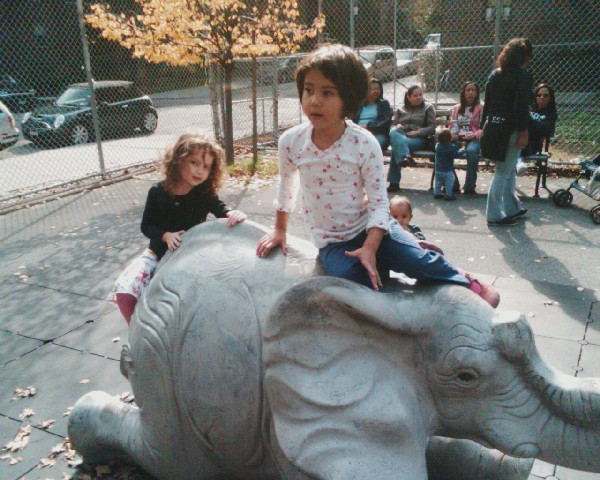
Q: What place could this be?
A: It is a park.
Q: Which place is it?
A: It is a park.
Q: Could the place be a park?
A: Yes, it is a park.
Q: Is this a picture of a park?
A: Yes, it is showing a park.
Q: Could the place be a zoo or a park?
A: It is a park.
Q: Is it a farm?
A: No, it is a park.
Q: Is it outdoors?
A: Yes, it is outdoors.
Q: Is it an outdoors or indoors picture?
A: It is outdoors.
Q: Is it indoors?
A: No, it is outdoors.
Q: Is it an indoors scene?
A: No, it is outdoors.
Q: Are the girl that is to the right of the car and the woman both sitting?
A: Yes, both the girl and the woman are sitting.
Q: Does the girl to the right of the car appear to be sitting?
A: Yes, the girl is sitting.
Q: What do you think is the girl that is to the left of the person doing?
A: The girl is sitting.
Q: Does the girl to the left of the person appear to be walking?
A: No, the girl is sitting.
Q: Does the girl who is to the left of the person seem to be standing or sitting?
A: The girl is sitting.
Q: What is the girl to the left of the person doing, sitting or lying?
A: The girl is sitting.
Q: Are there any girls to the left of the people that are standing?
A: Yes, there is a girl to the left of the people.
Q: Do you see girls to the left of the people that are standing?
A: Yes, there is a girl to the left of the people.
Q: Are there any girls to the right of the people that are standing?
A: No, the girl is to the left of the people.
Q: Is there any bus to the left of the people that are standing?
A: No, there is a girl to the left of the people.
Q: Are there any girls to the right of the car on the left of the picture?
A: Yes, there is a girl to the right of the car.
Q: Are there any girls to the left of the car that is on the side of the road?
A: No, the girl is to the right of the car.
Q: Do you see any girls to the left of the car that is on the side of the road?
A: No, the girl is to the right of the car.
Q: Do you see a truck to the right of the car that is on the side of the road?
A: No, there is a girl to the right of the car.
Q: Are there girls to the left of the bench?
A: Yes, there is a girl to the left of the bench.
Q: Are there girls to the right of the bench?
A: No, the girl is to the left of the bench.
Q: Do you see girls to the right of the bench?
A: No, the girl is to the left of the bench.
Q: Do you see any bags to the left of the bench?
A: No, there is a girl to the left of the bench.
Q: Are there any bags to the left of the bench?
A: No, there is a girl to the left of the bench.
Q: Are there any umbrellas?
A: No, there are no umbrellas.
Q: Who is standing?
A: The people are standing.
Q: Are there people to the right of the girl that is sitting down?
A: Yes, there are people to the right of the girl.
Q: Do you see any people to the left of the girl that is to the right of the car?
A: No, the people are to the right of the girl.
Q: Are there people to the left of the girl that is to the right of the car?
A: No, the people are to the right of the girl.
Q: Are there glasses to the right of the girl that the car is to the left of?
A: No, there are people to the right of the girl.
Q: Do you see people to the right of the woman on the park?
A: Yes, there are people to the right of the woman.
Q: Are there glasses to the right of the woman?
A: No, there are people to the right of the woman.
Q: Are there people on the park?
A: Yes, there are people on the park.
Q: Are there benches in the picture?
A: Yes, there is a bench.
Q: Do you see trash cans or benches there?
A: Yes, there is a bench.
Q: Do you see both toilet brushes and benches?
A: No, there is a bench but no toilet brushes.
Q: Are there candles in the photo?
A: No, there are no candles.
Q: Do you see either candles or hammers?
A: No, there are no candles or hammers.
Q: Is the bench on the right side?
A: Yes, the bench is on the right of the image.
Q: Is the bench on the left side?
A: No, the bench is on the right of the image.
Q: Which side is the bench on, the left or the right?
A: The bench is on the right of the image.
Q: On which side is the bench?
A: The bench is on the right of the image.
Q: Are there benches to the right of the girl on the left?
A: Yes, there is a bench to the right of the girl.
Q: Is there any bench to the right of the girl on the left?
A: Yes, there is a bench to the right of the girl.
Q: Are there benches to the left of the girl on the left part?
A: No, the bench is to the right of the girl.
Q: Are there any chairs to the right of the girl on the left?
A: No, there is a bench to the right of the girl.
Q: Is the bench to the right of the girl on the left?
A: Yes, the bench is to the right of the girl.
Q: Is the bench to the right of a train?
A: No, the bench is to the right of the girl.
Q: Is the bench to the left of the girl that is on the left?
A: No, the bench is to the right of the girl.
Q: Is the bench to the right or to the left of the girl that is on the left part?
A: The bench is to the right of the girl.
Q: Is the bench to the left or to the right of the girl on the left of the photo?
A: The bench is to the right of the girl.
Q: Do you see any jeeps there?
A: No, there are no jeeps.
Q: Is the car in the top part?
A: Yes, the car is in the top of the image.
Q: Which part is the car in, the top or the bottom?
A: The car is in the top of the image.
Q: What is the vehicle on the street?
A: The vehicle is a car.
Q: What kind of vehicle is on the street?
A: The vehicle is a car.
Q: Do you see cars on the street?
A: Yes, there is a car on the street.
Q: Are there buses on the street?
A: No, there is a car on the street.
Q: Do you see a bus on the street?
A: No, there is a car on the street.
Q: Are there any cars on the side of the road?
A: Yes, there is a car on the side of the road.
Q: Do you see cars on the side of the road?
A: Yes, there is a car on the side of the road.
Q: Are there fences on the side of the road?
A: No, there is a car on the side of the road.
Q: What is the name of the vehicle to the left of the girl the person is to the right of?
A: The vehicle is a car.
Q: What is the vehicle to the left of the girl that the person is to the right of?
A: The vehicle is a car.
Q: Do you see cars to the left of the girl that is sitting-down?
A: Yes, there is a car to the left of the girl.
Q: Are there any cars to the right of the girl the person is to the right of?
A: No, the car is to the left of the girl.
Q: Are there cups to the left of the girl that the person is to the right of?
A: No, there is a car to the left of the girl.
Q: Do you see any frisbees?
A: No, there are no frisbees.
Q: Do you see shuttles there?
A: No, there are no shuttles.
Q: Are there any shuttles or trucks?
A: No, there are no shuttles or trucks.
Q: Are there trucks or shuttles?
A: No, there are no shuttles or trucks.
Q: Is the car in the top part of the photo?
A: Yes, the car is in the top of the image.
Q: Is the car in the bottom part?
A: No, the car is in the top of the image.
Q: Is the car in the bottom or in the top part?
A: The car is in the top of the image.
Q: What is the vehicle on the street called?
A: The vehicle is a car.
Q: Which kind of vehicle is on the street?
A: The vehicle is a car.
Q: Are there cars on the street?
A: Yes, there is a car on the street.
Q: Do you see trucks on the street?
A: No, there is a car on the street.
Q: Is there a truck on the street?
A: No, there is a car on the street.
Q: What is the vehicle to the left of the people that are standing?
A: The vehicle is a car.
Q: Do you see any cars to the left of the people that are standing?
A: Yes, there is a car to the left of the people.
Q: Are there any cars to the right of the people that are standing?
A: No, the car is to the left of the people.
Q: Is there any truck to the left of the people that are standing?
A: No, there is a car to the left of the people.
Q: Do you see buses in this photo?
A: No, there are no buses.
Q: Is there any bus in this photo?
A: No, there are no buses.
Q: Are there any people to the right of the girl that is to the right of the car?
A: Yes, there is a person to the right of the girl.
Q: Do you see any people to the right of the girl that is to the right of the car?
A: Yes, there is a person to the right of the girl.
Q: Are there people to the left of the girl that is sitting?
A: No, the person is to the right of the girl.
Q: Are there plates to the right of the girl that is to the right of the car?
A: No, there is a person to the right of the girl.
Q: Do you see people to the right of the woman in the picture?
A: Yes, there is a person to the right of the woman.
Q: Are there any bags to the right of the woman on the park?
A: No, there is a person to the right of the woman.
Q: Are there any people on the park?
A: Yes, there is a person on the park.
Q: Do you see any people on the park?
A: Yes, there is a person on the park.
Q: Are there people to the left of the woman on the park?
A: Yes, there is a person to the left of the woman.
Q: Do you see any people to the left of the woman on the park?
A: Yes, there is a person to the left of the woman.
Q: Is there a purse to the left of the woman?
A: No, there is a person to the left of the woman.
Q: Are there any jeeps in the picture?
A: No, there are no jeeps.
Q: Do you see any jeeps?
A: No, there are no jeeps.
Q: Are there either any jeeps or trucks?
A: No, there are no jeeps or trucks.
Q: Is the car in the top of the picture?
A: Yes, the car is in the top of the image.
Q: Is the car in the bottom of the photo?
A: No, the car is in the top of the image.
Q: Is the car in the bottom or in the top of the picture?
A: The car is in the top of the image.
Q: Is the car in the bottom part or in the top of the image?
A: The car is in the top of the image.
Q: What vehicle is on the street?
A: The vehicle is a car.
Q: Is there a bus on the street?
A: No, there is a car on the street.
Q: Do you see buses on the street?
A: No, there is a car on the street.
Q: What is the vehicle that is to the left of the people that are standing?
A: The vehicle is a car.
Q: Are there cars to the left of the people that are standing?
A: Yes, there is a car to the left of the people.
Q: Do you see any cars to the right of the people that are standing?
A: No, the car is to the left of the people.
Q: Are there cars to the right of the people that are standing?
A: No, the car is to the left of the people.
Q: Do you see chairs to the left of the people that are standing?
A: No, there is a car to the left of the people.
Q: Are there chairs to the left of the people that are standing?
A: No, there is a car to the left of the people.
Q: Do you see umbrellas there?
A: No, there are no umbrellas.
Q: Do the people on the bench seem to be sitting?
A: Yes, the people are sitting.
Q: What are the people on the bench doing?
A: The people are sitting.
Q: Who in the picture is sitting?
A: The people are sitting.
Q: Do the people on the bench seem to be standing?
A: No, the people are sitting.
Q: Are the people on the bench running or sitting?
A: The people are sitting.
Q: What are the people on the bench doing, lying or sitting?
A: The people are sitting.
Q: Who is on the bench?
A: The people are on the bench.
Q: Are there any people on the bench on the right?
A: Yes, there are people on the bench.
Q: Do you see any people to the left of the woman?
A: Yes, there are people to the left of the woman.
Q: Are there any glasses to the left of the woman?
A: No, there are people to the left of the woman.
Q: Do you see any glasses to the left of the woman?
A: No, there are people to the left of the woman.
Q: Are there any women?
A: Yes, there is a woman.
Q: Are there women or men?
A: Yes, there is a woman.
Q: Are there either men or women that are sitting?
A: Yes, the woman is sitting.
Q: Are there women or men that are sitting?
A: Yes, the woman is sitting.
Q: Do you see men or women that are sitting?
A: Yes, the woman is sitting.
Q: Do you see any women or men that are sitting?
A: Yes, the woman is sitting.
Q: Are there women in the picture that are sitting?
A: Yes, there is a woman that is sitting.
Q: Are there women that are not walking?
A: Yes, there is a woman that is sitting.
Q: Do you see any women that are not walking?
A: Yes, there is a woman that is sitting .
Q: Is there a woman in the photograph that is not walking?
A: Yes, there is a woman that is sitting.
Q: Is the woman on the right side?
A: Yes, the woman is on the right of the image.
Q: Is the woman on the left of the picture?
A: No, the woman is on the right of the image.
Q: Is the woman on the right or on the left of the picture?
A: The woman is on the right of the image.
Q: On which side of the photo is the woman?
A: The woman is on the right of the image.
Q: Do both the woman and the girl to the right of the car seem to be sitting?
A: Yes, both the woman and the girl are sitting.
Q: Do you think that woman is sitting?
A: Yes, the woman is sitting.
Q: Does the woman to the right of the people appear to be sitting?
A: Yes, the woman is sitting.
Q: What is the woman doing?
A: The woman is sitting.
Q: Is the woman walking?
A: No, the woman is sitting.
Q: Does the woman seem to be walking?
A: No, the woman is sitting.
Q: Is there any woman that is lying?
A: No, there is a woman but she is sitting.